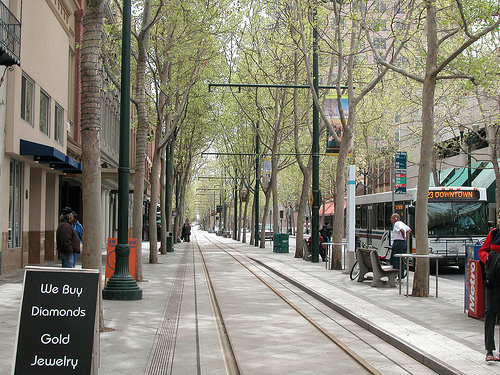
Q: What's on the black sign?
A: White writing.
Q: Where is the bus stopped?
A: At the side of the road on right.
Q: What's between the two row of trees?
A: Train tracks.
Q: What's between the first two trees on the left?
A: Green old fashioned light pole.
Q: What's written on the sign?
A: We buy diamonds gold jewelry sign.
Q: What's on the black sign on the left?
A: White writing.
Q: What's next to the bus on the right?
A: Row of tall trees.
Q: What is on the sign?
A: Jewelry store.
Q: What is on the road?
A: Passenger bus.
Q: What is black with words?
A: A sign.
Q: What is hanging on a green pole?
A: Sign.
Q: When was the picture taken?
A: Daytime.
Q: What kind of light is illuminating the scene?
A: Sunlight.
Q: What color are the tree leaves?
A: Green.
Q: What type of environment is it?
A: Urban.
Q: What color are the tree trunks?
A: Brown.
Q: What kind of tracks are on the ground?
A: Train tracks.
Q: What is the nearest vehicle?
A: A bus.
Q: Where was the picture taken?
A: On the street.